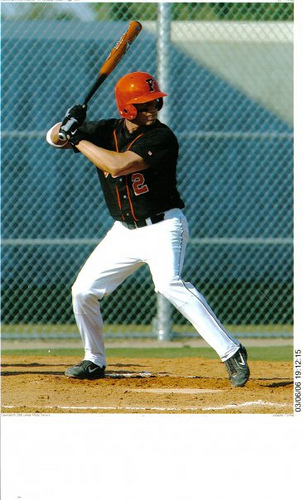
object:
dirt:
[3, 362, 290, 411]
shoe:
[225, 343, 250, 388]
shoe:
[65, 359, 106, 380]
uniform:
[71, 117, 241, 368]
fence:
[1, 0, 294, 338]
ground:
[0, 311, 294, 414]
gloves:
[59, 114, 84, 145]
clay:
[11, 378, 292, 419]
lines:
[31, 400, 287, 411]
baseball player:
[46, 71, 251, 388]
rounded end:
[100, 16, 143, 74]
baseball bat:
[57, 19, 143, 142]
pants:
[71, 207, 240, 368]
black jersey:
[70, 117, 185, 223]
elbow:
[107, 161, 125, 176]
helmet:
[114, 71, 168, 120]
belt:
[121, 212, 164, 230]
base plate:
[128, 386, 224, 395]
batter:
[45, 72, 249, 386]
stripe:
[6, 398, 293, 410]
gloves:
[62, 104, 88, 128]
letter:
[146, 78, 156, 92]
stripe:
[112, 127, 138, 221]